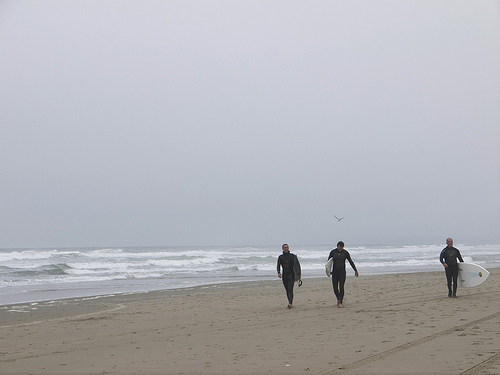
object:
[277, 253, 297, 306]
wet suit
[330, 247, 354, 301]
wet suit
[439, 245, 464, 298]
wet suit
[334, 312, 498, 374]
track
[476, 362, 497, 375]
track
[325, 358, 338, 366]
footprint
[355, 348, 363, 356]
footprint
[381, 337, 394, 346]
footprint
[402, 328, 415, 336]
footprint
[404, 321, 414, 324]
footprint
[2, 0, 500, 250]
sky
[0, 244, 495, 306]
water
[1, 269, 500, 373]
beach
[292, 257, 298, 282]
surfboard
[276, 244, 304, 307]
man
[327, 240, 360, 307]
man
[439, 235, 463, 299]
man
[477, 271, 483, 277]
logo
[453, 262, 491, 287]
surf board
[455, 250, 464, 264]
arm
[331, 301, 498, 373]
tire tracks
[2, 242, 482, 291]
waves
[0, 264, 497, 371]
shore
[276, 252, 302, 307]
wetssuits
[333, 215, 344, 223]
white plate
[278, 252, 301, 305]
wetsuits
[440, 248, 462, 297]
wetsuit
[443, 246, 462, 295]
wetsuits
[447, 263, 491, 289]
surfboard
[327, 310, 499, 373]
tracks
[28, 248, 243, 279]
ocean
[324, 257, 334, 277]
surfboard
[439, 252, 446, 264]
arm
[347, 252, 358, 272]
arm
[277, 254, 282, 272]
arm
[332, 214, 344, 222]
bird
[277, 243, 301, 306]
suit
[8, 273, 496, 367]
sand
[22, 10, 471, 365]
daytime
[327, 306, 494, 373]
track mark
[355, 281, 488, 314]
track mark